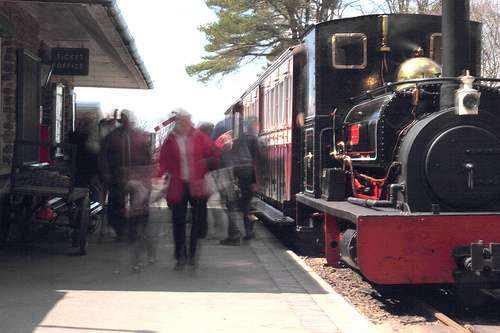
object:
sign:
[51, 47, 89, 75]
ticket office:
[0, 0, 73, 244]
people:
[83, 107, 279, 278]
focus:
[66, 103, 269, 282]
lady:
[142, 107, 240, 275]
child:
[122, 173, 158, 270]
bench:
[4, 178, 109, 256]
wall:
[0, 0, 76, 245]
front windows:
[332, 33, 442, 70]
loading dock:
[239, 193, 297, 228]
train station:
[0, 0, 409, 330]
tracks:
[397, 280, 496, 331]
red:
[221, 0, 500, 290]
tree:
[189, 0, 354, 82]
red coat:
[145, 121, 227, 204]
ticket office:
[56, 52, 84, 69]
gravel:
[254, 213, 500, 332]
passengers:
[297, 55, 315, 135]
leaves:
[185, 0, 270, 87]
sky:
[73, 0, 500, 151]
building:
[0, 0, 155, 256]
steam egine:
[344, 0, 500, 213]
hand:
[220, 130, 238, 149]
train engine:
[296, 0, 498, 285]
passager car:
[220, 42, 303, 245]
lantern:
[453, 69, 482, 115]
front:
[353, 0, 499, 288]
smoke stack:
[439, 0, 475, 108]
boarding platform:
[248, 196, 296, 224]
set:
[407, 287, 499, 333]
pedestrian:
[100, 106, 155, 275]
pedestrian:
[210, 114, 271, 247]